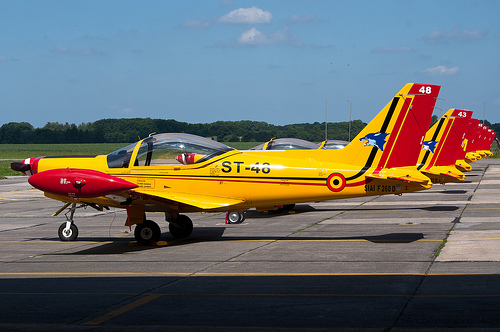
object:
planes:
[11, 81, 441, 243]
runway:
[0, 151, 500, 330]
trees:
[2, 118, 36, 147]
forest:
[0, 115, 498, 144]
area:
[1, 140, 497, 330]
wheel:
[55, 222, 79, 242]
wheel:
[130, 219, 160, 246]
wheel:
[166, 215, 194, 235]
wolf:
[358, 131, 390, 152]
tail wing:
[342, 81, 440, 165]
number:
[259, 162, 272, 176]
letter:
[219, 161, 232, 173]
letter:
[233, 161, 245, 174]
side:
[17, 147, 420, 196]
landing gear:
[56, 204, 80, 244]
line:
[68, 288, 167, 330]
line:
[0, 271, 498, 278]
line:
[1, 236, 500, 245]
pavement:
[0, 169, 499, 329]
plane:
[173, 108, 474, 225]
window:
[105, 132, 237, 171]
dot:
[333, 179, 339, 185]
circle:
[330, 176, 340, 187]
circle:
[323, 172, 348, 192]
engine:
[26, 168, 139, 200]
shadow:
[22, 222, 424, 255]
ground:
[0, 141, 498, 330]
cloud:
[219, 2, 273, 25]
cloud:
[231, 28, 265, 48]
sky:
[0, 0, 499, 124]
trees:
[41, 122, 78, 144]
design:
[324, 171, 347, 193]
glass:
[106, 132, 232, 166]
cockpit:
[104, 134, 238, 168]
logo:
[356, 131, 392, 153]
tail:
[411, 107, 474, 166]